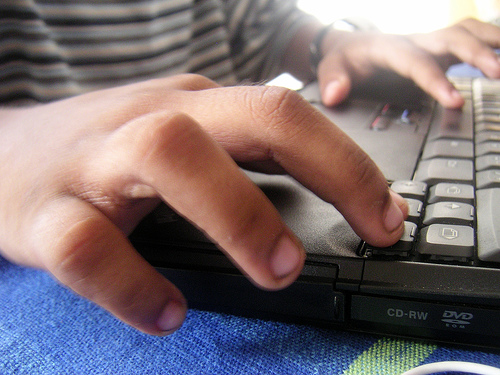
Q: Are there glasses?
A: No, there are no glasses.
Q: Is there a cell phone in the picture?
A: No, there are no cell phones.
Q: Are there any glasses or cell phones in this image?
A: No, there are no cell phones or glasses.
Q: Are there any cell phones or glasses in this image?
A: No, there are no cell phones or glasses.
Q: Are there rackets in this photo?
A: No, there are no rackets.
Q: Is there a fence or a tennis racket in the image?
A: No, there are no rackets or fences.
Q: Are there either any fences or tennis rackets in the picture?
A: No, there are no tennis rackets or fences.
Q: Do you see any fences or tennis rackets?
A: No, there are no tennis rackets or fences.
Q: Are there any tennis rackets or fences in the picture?
A: No, there are no tennis rackets or fences.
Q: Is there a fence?
A: No, there are no fences.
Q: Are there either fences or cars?
A: No, there are no fences or cars.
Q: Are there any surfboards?
A: No, there are no surfboards.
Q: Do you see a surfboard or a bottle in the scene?
A: No, there are no surfboards or bottles.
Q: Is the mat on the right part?
A: Yes, the mat is on the right of the image.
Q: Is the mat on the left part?
A: No, the mat is on the right of the image.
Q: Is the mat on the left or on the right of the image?
A: The mat is on the right of the image.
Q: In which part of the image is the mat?
A: The mat is on the right of the image.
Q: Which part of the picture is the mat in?
A: The mat is on the right of the image.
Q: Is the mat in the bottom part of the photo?
A: Yes, the mat is in the bottom of the image.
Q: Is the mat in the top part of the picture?
A: No, the mat is in the bottom of the image.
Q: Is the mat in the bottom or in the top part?
A: The mat is in the bottom of the image.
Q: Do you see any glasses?
A: No, there are no glasses.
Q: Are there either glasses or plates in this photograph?
A: No, there are no glasses or plates.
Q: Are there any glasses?
A: No, there are no glasses.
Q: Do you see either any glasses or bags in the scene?
A: No, there are no glasses or bags.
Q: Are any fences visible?
A: No, there are no fences.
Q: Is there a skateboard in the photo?
A: No, there are no skateboards.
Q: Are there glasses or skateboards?
A: No, there are no skateboards or glasses.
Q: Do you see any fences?
A: No, there are no fences.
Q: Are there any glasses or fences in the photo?
A: No, there are no fences or glasses.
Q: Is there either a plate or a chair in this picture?
A: No, there are no chairs or plates.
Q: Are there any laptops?
A: Yes, there is a laptop.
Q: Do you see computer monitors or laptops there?
A: Yes, there is a laptop.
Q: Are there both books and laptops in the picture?
A: No, there is a laptop but no books.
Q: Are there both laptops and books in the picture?
A: No, there is a laptop but no books.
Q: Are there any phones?
A: No, there are no phones.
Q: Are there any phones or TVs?
A: No, there are no phones or tvs.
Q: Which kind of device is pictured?
A: The device is a laptop.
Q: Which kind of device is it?
A: The device is a laptop.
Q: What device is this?
A: This is a laptop.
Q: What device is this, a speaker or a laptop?
A: This is a laptop.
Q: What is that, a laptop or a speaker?
A: That is a laptop.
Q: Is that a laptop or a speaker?
A: That is a laptop.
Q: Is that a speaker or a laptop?
A: That is a laptop.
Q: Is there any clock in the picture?
A: No, there are no clocks.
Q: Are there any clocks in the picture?
A: No, there are no clocks.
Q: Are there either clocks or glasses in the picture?
A: No, there are no clocks or glasses.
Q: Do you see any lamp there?
A: No, there are no lamps.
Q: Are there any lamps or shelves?
A: No, there are no lamps or shelves.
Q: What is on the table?
A: The cord is on the table.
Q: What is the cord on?
A: The cord is on the table.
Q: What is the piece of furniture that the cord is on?
A: The piece of furniture is a table.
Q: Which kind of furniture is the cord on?
A: The cord is on the table.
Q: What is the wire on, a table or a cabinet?
A: The wire is on a table.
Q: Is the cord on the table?
A: Yes, the cord is on the table.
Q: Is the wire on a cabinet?
A: No, the wire is on the table.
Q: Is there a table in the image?
A: Yes, there is a table.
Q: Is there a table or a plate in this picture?
A: Yes, there is a table.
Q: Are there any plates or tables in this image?
A: Yes, there is a table.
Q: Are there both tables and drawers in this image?
A: No, there is a table but no drawers.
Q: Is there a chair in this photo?
A: No, there are no chairs.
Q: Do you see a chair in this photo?
A: No, there are no chairs.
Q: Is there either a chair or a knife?
A: No, there are no chairs or knives.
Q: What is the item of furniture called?
A: The piece of furniture is a table.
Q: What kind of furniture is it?
A: The piece of furniture is a table.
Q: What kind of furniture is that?
A: This is a table.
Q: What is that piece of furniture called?
A: This is a table.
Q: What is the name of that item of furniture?
A: This is a table.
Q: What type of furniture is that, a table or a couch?
A: This is a table.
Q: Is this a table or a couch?
A: This is a table.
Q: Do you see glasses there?
A: No, there are no glasses.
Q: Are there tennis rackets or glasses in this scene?
A: No, there are no glasses or tennis rackets.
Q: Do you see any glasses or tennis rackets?
A: No, there are no glasses or tennis rackets.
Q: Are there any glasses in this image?
A: No, there are no glasses.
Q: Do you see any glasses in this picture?
A: No, there are no glasses.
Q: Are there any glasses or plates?
A: No, there are no glasses or plates.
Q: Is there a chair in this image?
A: No, there are no chairs.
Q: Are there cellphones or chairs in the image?
A: No, there are no chairs or cellphones.